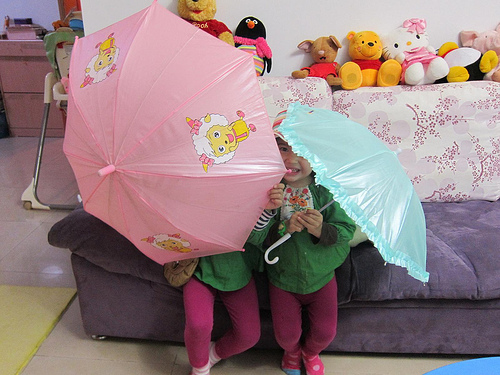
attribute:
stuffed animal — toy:
[182, 0, 237, 48]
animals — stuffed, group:
[312, 23, 461, 88]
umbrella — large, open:
[55, 1, 287, 264]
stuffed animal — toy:
[177, 0, 234, 48]